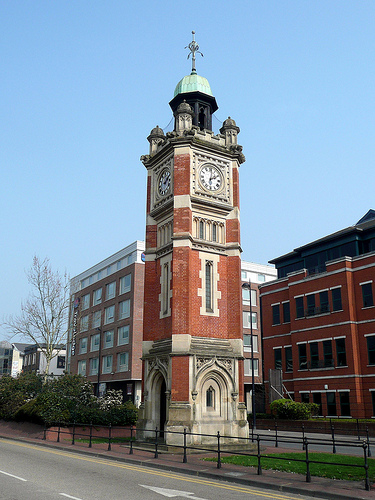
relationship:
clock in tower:
[189, 149, 234, 211] [132, 30, 251, 448]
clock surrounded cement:
[189, 149, 234, 211] [188, 143, 235, 216]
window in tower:
[204, 384, 220, 412] [132, 30, 251, 448]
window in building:
[119, 302, 133, 322] [62, 239, 276, 417]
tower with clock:
[132, 30, 251, 448] [189, 149, 234, 211]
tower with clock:
[132, 30, 251, 448] [148, 155, 179, 207]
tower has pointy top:
[132, 30, 251, 448] [169, 30, 218, 99]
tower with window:
[132, 30, 251, 448] [204, 384, 220, 412]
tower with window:
[132, 30, 251, 448] [202, 258, 215, 318]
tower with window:
[132, 30, 251, 448] [155, 262, 172, 320]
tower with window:
[132, 30, 251, 448] [210, 218, 220, 243]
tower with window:
[132, 30, 251, 448] [198, 218, 208, 241]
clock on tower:
[189, 149, 234, 211] [132, 30, 251, 448]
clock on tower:
[148, 155, 179, 207] [132, 30, 251, 448]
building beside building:
[62, 239, 276, 417] [259, 251, 374, 420]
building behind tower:
[62, 239, 276, 417] [132, 30, 251, 448]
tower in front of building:
[132, 30, 251, 448] [62, 239, 276, 417]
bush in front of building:
[268, 400, 319, 420] [259, 251, 374, 420]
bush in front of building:
[88, 394, 141, 428] [62, 239, 276, 417]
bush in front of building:
[30, 372, 100, 427] [62, 239, 276, 417]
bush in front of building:
[2, 370, 45, 419] [62, 239, 276, 417]